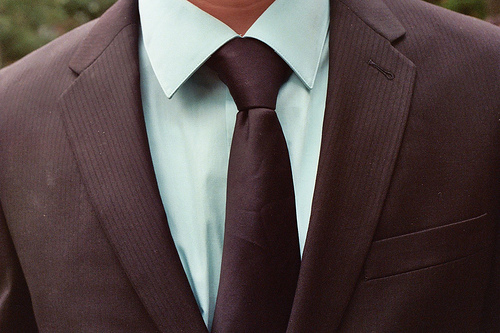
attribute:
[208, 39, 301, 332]
tie — brown, black, navy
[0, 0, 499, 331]
coat — brown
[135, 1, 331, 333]
shirt — white, blue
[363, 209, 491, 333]
pocket — breast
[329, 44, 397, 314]
stripe — tiny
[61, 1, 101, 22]
bench — black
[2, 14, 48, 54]
tree — green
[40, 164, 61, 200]
spot — white